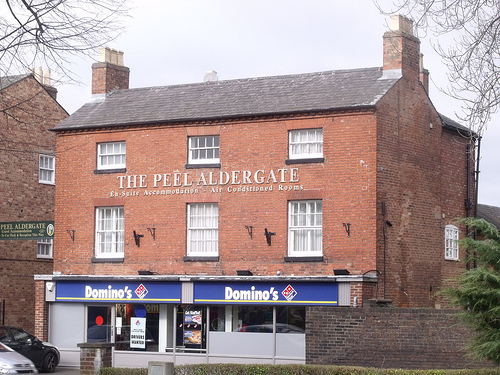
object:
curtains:
[92, 207, 123, 260]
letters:
[117, 167, 299, 188]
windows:
[92, 206, 125, 259]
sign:
[58, 281, 182, 303]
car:
[4, 328, 58, 372]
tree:
[411, 4, 499, 305]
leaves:
[454, 112, 463, 121]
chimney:
[92, 47, 129, 98]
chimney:
[381, 15, 421, 80]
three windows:
[95, 127, 323, 171]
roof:
[53, 65, 394, 132]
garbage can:
[147, 359, 177, 374]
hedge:
[179, 364, 379, 374]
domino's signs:
[55, 276, 339, 306]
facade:
[54, 131, 379, 278]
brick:
[326, 113, 375, 273]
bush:
[102, 366, 147, 374]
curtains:
[95, 141, 125, 171]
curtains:
[188, 136, 221, 164]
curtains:
[287, 129, 323, 160]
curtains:
[185, 202, 218, 259]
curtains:
[287, 199, 323, 256]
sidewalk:
[48, 367, 240, 374]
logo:
[134, 283, 149, 300]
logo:
[280, 284, 298, 301]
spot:
[95, 316, 103, 325]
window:
[185, 133, 223, 167]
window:
[285, 124, 326, 167]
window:
[183, 200, 222, 262]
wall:
[304, 305, 472, 359]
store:
[32, 267, 358, 361]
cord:
[383, 203, 389, 300]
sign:
[0, 220, 54, 241]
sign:
[190, 280, 341, 306]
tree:
[0, 1, 110, 86]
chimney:
[44, 69, 57, 100]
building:
[4, 69, 64, 167]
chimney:
[420, 54, 430, 86]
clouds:
[100, 1, 339, 83]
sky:
[9, 1, 490, 83]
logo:
[183, 310, 203, 325]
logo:
[134, 304, 147, 317]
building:
[28, 16, 483, 367]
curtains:
[445, 224, 459, 259]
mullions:
[444, 224, 460, 262]